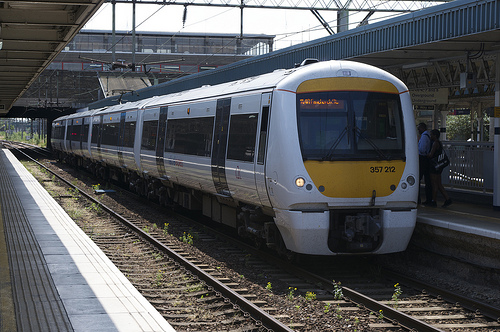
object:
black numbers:
[369, 165, 397, 173]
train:
[50, 59, 420, 257]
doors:
[209, 96, 233, 200]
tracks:
[314, 266, 499, 331]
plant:
[374, 309, 386, 322]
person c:
[427, 129, 454, 208]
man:
[415, 122, 433, 207]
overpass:
[67, 35, 279, 60]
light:
[295, 177, 305, 187]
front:
[265, 60, 418, 256]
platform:
[0, 146, 174, 332]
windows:
[99, 122, 120, 146]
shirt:
[418, 131, 431, 156]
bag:
[426, 131, 450, 171]